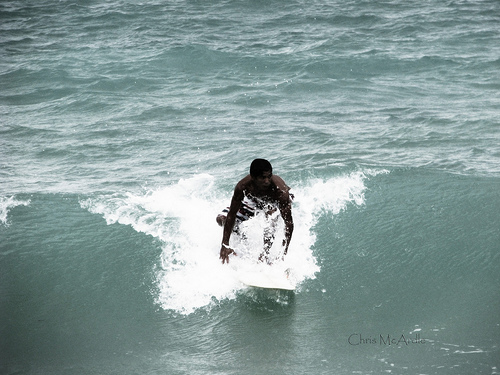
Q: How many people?
A: One.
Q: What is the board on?
A: Waves.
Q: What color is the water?
A: Blue.